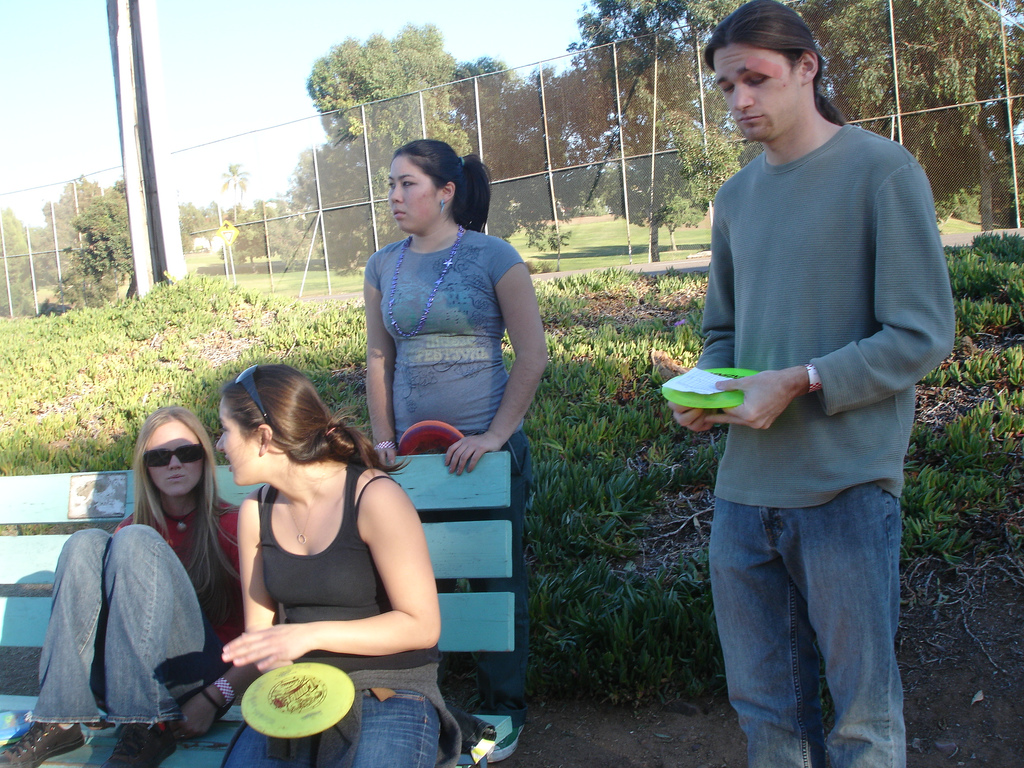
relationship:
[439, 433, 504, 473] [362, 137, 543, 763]
girl hand on woman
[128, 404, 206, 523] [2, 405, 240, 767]
girl head of woman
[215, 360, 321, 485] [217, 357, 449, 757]
girl head of girl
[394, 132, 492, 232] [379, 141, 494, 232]
hair on head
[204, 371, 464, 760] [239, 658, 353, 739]
girl holding frisbee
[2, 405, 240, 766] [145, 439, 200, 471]
woman wearing glasses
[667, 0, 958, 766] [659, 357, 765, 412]
man holding frisbee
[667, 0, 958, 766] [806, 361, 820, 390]
man has bracelet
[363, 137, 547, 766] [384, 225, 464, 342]
woman wearing necklace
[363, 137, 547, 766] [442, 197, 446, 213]
woman wearing earrings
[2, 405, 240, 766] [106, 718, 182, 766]
woman wearing shoe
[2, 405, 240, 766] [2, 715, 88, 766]
woman wearing shoe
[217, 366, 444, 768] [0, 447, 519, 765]
girl sitting on bench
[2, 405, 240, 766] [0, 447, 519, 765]
woman sitting on bench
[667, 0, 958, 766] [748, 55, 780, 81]
man with band-aid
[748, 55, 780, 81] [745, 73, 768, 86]
band-aid above eye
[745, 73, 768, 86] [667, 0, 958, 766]
eye of man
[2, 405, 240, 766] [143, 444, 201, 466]
woman has glasses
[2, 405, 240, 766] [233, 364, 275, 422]
woman has sunglasses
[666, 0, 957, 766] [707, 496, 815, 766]
boy has leg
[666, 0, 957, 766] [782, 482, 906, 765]
boy has leg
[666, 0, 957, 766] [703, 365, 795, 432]
boy has hand